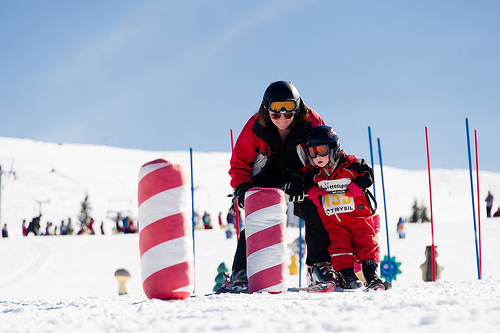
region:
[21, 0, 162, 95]
a light blue sky.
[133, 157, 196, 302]
a red and white marker.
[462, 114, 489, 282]
two thin blue and red markers.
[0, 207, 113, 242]
a small crowd of people.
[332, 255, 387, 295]
a baby boy is wearing black boots.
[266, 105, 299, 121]
a woman is wearing goggle glasses.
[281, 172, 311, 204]
a little boy is wearing black gloves.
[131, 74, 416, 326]
a woman and baby is going skiing.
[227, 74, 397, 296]
a mother teaching her child to ski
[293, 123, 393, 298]
a child learning to ski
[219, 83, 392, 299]
a woman behind a child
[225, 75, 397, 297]
a woman and child wearing ski clothes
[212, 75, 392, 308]
a woman and child on skis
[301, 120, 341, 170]
a child wearing a ski helmet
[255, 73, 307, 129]
a woman wearing a ski helmet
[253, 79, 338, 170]
a woman and child wearing black ski helmets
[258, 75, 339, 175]
a woman and child wearing ski helmets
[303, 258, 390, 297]
the ski boots of a woman and a child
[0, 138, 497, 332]
the snow all over the ground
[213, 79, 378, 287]
the woman and child on the snow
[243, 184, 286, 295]
the ride and white object on the snow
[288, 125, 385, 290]
the small child on the snow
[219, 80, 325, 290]
the adult helping the small child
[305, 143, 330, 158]
the protective eyewear on the child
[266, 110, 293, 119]
the sunglasses on the woman's face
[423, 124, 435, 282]
the red stick sticking out of the snow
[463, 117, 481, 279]
the blue stick sticking out of the snow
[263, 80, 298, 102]
the helmet on the woman's head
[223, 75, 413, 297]
a woman standing by a little boy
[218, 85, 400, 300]
two people on the snow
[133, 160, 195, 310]
red and white stripes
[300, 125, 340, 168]
black helmet on the head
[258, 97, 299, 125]
goggles sitting above the sunglasses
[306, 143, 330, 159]
red tint on the goggles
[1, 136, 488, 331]
ground is covered in white snow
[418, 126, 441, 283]
skinny red pole sticking out of the snow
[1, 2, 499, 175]
pale blue sky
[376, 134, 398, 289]
skinny blue pole sticking out of the ground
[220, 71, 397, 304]
a kid next to an adult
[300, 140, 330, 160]
goggles are tinted red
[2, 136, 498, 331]
snow covering the ground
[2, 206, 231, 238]
several people in the background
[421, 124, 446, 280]
skinny red pole sticking out of the ground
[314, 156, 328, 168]
mouth is slightly open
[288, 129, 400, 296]
kid wearing a red snowsuit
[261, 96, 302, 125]
goggles above the sunglasses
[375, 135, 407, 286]
skinny blue pole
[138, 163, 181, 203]
red stripe on pole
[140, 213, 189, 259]
red stripe on pole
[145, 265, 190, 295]
red stripe on pole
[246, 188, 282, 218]
red stripe on pole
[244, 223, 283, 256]
red stripe on pole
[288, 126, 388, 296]
a child on skis